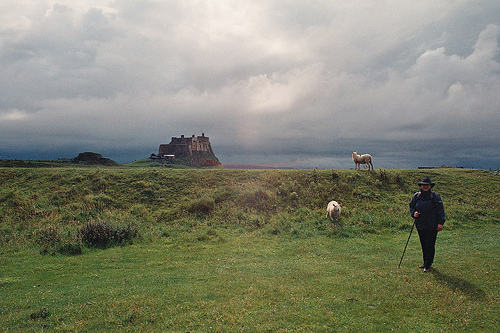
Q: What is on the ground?
A: Grass.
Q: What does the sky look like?
A: Cloudy.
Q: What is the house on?
A: Hill.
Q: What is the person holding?
A: A stick.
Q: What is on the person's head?
A: A hat.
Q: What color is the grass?
A: Green.